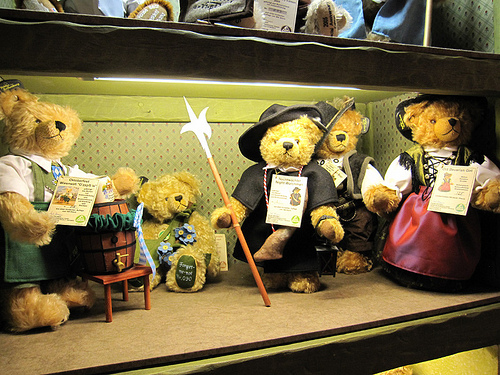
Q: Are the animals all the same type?
A: Yes, all the animals are bears.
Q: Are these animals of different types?
A: No, all the animals are bears.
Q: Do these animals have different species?
A: No, all the animals are bears.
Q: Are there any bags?
A: No, there are no bags.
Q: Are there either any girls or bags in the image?
A: No, there are no bags or girls.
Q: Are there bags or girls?
A: No, there are no bags or girls.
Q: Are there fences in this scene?
A: No, there are no fences.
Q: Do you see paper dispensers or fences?
A: No, there are no fences or paper dispensers.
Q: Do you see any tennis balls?
A: No, there are no tennis balls.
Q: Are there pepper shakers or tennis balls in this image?
A: No, there are no tennis balls or pepper shakers.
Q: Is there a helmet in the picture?
A: No, there are no helmets.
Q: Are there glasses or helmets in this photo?
A: No, there are no helmets or glasses.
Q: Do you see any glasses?
A: No, there are no glasses.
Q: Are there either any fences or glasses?
A: No, there are no glasses or fences.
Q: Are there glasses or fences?
A: No, there are no glasses or fences.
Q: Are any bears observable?
A: Yes, there is a bear.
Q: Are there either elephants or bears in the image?
A: Yes, there is a bear.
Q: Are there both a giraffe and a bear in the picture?
A: No, there is a bear but no giraffes.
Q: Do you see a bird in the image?
A: No, there are no birds.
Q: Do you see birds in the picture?
A: No, there are no birds.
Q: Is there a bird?
A: No, there are no birds.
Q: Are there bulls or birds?
A: No, there are no birds or bulls.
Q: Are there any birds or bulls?
A: No, there are no birds or bulls.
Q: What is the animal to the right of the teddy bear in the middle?
A: The animal is a bear.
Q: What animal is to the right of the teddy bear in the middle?
A: The animal is a bear.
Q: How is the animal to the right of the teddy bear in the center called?
A: The animal is a bear.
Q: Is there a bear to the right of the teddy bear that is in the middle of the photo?
A: Yes, there is a bear to the right of the teddy bear.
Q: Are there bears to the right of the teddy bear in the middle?
A: Yes, there is a bear to the right of the teddy bear.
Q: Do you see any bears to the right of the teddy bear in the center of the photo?
A: Yes, there is a bear to the right of the teddy bear.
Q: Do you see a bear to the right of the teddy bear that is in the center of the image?
A: Yes, there is a bear to the right of the teddy bear.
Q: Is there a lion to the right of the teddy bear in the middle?
A: No, there is a bear to the right of the teddy bear.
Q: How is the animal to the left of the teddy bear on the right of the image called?
A: The animal is a bear.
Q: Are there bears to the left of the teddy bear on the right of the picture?
A: Yes, there is a bear to the left of the teddy bear.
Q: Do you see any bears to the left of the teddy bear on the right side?
A: Yes, there is a bear to the left of the teddy bear.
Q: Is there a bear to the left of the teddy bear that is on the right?
A: Yes, there is a bear to the left of the teddy bear.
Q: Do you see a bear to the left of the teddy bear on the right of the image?
A: Yes, there is a bear to the left of the teddy bear.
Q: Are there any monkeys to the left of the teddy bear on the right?
A: No, there is a bear to the left of the teddy bear.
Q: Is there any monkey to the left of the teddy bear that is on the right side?
A: No, there is a bear to the left of the teddy bear.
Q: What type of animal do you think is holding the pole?
A: The animal is a bear.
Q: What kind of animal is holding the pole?
A: The animal is a bear.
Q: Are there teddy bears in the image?
A: Yes, there is a teddy bear.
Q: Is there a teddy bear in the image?
A: Yes, there is a teddy bear.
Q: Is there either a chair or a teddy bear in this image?
A: Yes, there is a teddy bear.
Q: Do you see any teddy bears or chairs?
A: Yes, there is a teddy bear.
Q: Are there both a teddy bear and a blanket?
A: No, there is a teddy bear but no blankets.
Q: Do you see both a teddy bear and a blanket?
A: No, there is a teddy bear but no blankets.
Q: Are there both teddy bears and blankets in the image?
A: No, there is a teddy bear but no blankets.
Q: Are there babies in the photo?
A: No, there are no babies.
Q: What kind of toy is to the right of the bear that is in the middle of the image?
A: The toy is a teddy bear.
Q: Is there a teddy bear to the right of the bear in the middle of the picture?
A: Yes, there is a teddy bear to the right of the bear.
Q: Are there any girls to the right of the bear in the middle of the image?
A: No, there is a teddy bear to the right of the bear.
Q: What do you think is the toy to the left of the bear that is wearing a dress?
A: The toy is a teddy bear.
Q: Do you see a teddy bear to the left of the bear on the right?
A: Yes, there is a teddy bear to the left of the bear.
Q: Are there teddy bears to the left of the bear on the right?
A: Yes, there is a teddy bear to the left of the bear.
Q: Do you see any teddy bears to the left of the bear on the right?
A: Yes, there is a teddy bear to the left of the bear.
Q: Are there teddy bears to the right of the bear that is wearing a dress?
A: No, the teddy bear is to the left of the bear.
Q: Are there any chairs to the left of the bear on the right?
A: No, there is a teddy bear to the left of the bear.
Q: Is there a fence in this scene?
A: No, there are no fences.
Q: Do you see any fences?
A: No, there are no fences.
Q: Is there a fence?
A: No, there are no fences.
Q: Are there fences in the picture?
A: No, there are no fences.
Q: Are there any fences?
A: No, there are no fences.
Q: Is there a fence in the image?
A: No, there are no fences.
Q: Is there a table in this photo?
A: Yes, there is a table.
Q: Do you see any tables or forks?
A: Yes, there is a table.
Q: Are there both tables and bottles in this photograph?
A: No, there is a table but no bottles.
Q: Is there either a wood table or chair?
A: Yes, there is a wood table.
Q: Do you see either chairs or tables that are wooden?
A: Yes, the table is wooden.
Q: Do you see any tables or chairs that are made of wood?
A: Yes, the table is made of wood.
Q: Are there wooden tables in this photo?
A: Yes, there is a wood table.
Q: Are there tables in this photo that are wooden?
A: Yes, there is a table that is wooden.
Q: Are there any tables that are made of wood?
A: Yes, there is a table that is made of wood.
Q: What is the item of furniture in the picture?
A: The piece of furniture is a table.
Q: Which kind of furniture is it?
A: The piece of furniture is a table.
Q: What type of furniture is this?
A: This is a table.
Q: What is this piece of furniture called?
A: This is a table.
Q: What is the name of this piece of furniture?
A: This is a table.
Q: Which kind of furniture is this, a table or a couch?
A: This is a table.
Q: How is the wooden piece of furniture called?
A: The piece of furniture is a table.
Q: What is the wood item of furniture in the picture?
A: The piece of furniture is a table.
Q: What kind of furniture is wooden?
A: The furniture is a table.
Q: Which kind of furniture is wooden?
A: The furniture is a table.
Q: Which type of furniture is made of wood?
A: The furniture is a table.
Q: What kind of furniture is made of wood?
A: The furniture is a table.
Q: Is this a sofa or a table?
A: This is a table.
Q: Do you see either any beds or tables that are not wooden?
A: No, there is a table but it is wooden.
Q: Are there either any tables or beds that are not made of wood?
A: No, there is a table but it is made of wood.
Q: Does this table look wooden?
A: Yes, the table is wooden.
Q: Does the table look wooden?
A: Yes, the table is wooden.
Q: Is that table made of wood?
A: Yes, the table is made of wood.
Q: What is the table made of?
A: The table is made of wood.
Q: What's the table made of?
A: The table is made of wood.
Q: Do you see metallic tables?
A: No, there is a table but it is wooden.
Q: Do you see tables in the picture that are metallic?
A: No, there is a table but it is wooden.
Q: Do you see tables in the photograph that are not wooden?
A: No, there is a table but it is wooden.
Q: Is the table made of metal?
A: No, the table is made of wood.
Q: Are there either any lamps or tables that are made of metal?
A: No, there is a table but it is made of wood.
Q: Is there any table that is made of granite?
A: No, there is a table but it is made of wood.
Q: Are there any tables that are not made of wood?
A: No, there is a table but it is made of wood.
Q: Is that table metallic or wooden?
A: The table is wooden.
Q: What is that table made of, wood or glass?
A: The table is made of wood.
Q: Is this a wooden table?
A: Yes, this is a wooden table.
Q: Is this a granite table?
A: No, this is a wooden table.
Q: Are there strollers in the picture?
A: No, there are no strollers.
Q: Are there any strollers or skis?
A: No, there are no strollers or skis.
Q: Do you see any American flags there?
A: No, there are no American flags.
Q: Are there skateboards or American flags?
A: No, there are no American flags or skateboards.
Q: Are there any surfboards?
A: No, there are no surfboards.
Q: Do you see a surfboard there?
A: No, there are no surfboards.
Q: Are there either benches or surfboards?
A: No, there are no surfboards or benches.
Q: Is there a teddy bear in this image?
A: Yes, there is a teddy bear.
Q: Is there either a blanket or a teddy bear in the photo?
A: Yes, there is a teddy bear.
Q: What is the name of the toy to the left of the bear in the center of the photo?
A: The toy is a teddy bear.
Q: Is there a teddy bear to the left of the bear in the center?
A: Yes, there is a teddy bear to the left of the bear.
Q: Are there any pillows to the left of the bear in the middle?
A: No, there is a teddy bear to the left of the bear.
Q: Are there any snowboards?
A: No, there are no snowboards.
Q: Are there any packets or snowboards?
A: No, there are no snowboards or packets.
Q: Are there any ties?
A: Yes, there is a tie.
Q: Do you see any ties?
A: Yes, there is a tie.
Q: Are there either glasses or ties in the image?
A: Yes, there is a tie.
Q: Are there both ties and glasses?
A: No, there is a tie but no glasses.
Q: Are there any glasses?
A: No, there are no glasses.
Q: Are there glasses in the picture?
A: No, there are no glasses.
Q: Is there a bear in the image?
A: Yes, there is a bear.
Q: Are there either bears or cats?
A: Yes, there is a bear.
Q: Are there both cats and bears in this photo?
A: No, there is a bear but no cats.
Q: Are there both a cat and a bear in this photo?
A: No, there is a bear but no cats.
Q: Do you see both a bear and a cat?
A: No, there is a bear but no cats.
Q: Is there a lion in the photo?
A: No, there are no lions.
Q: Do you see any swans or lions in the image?
A: No, there are no lions or swans.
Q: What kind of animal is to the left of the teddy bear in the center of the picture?
A: The animal is a bear.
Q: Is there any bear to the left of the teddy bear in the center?
A: Yes, there is a bear to the left of the teddy bear.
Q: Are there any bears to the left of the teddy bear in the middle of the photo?
A: Yes, there is a bear to the left of the teddy bear.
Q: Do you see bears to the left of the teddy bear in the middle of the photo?
A: Yes, there is a bear to the left of the teddy bear.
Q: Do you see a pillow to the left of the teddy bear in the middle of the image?
A: No, there is a bear to the left of the teddy bear.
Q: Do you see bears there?
A: Yes, there is a bear.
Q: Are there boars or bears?
A: Yes, there is a bear.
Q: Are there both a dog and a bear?
A: No, there is a bear but no dogs.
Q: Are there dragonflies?
A: No, there are no dragonflies.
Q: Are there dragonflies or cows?
A: No, there are no dragonflies or cows.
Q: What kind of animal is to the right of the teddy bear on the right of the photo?
A: The animal is a bear.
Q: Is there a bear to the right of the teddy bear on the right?
A: Yes, there is a bear to the right of the teddy bear.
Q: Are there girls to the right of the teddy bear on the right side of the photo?
A: No, there is a bear to the right of the teddy bear.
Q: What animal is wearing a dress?
A: The bear is wearing a dress.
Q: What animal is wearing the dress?
A: The bear is wearing a dress.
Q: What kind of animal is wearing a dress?
A: The animal is a bear.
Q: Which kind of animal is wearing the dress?
A: The animal is a bear.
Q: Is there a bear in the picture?
A: Yes, there is a bear.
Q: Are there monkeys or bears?
A: Yes, there is a bear.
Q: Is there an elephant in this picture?
A: No, there are no elephants.